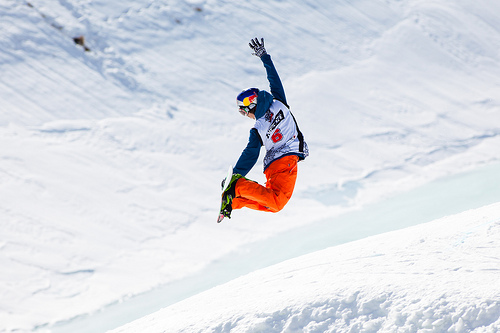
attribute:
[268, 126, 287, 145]
number — red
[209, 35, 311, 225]
person — wearing, jumping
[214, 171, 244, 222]
shoes — green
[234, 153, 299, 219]
pants — orange 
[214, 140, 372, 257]
pants — orange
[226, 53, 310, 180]
coat — blue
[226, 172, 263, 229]
shoes — green 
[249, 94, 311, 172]
top — white 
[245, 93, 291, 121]
hood — blue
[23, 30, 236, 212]
snow — white 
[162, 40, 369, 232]
person — jumping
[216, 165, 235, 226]
snow board — white , long 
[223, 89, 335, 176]
top — blue , white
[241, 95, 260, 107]
logo — red 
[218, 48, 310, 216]
jacket — blue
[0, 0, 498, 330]
snow — covering, white 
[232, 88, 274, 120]
helmet — blue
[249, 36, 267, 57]
glove — blue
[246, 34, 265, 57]
glove — white, black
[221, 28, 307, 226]
person — wearing